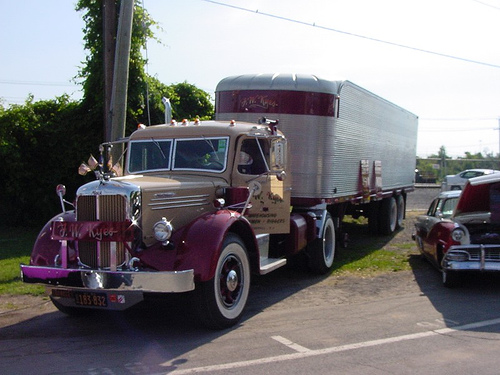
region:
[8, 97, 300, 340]
The purple and tan truck cab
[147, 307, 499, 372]
The white lines on the ground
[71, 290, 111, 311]
The license plate of the truck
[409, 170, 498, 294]
The white and red car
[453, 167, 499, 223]
The hood of the white and red car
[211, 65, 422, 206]
The trailer behind the truck cab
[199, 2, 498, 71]
The wires passing over the cars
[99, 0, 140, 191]
The poles behind the cab of the truck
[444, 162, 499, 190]
The white care in the background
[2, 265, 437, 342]
The dirt between the street and the grass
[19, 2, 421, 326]
Purple, gold and white horse truck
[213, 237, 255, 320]
Front left wheel of truck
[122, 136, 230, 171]
Front windshield of big truck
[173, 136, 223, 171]
Left front windshield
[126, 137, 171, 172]
Right front windshield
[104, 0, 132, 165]
Big rig exhaust pipe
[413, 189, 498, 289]
Car parked next to the big rig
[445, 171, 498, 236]
Opened hood of car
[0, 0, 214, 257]
Trees on the side of the big rig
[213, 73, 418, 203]
White cattle trailer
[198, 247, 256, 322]
it is the front tire of the truck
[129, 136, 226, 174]
it is the wind shield of the truck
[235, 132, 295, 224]
it is the door of the truck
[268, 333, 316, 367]
white lines on the road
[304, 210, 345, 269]
the middle wheel of the truck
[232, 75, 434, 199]
a grey trailer on back of the truck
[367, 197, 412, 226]
rear tires of the big truck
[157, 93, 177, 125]
horn on top of the truck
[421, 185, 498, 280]
a car beside the truck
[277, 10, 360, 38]
a power line up above the truck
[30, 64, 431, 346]
truck that is parked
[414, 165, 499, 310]
hood of the car is up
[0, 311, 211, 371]
shadow on the ground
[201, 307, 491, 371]
white line on the ground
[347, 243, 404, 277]
small patch of grass on the ground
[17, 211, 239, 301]
purple paint on the front of the truck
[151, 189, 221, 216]
silver lines on the truck cab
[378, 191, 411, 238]
two wheels on the back of the truck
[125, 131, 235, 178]
white outline around the windows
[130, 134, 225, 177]
windows on the front of the truck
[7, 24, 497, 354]
Picture taken outdoors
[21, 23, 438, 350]
Picture taken during the day.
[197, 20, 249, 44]
The sky is void of clouds.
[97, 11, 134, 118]
A large telephone pole.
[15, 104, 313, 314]
A older truck.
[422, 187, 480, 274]
A classic car.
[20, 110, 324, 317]
The truck is an older classic.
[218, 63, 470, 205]
A older trailer.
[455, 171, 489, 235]
The hood to the engine is up.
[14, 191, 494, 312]
The truck and car are not moving.